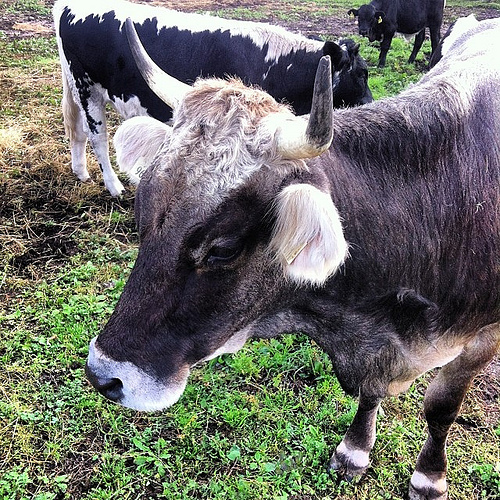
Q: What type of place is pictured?
A: It is a field.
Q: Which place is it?
A: It is a field.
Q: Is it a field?
A: Yes, it is a field.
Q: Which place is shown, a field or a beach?
A: It is a field.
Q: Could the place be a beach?
A: No, it is a field.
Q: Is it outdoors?
A: Yes, it is outdoors.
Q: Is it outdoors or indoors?
A: It is outdoors.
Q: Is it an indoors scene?
A: No, it is outdoors.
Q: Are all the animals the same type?
A: Yes, all the animals are cows.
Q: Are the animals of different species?
A: No, all the animals are cows.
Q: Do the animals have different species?
A: No, all the animals are cows.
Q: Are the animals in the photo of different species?
A: No, all the animals are cows.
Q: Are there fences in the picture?
A: No, there are no fences.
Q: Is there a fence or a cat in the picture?
A: No, there are no fences or cats.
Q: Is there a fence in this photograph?
A: No, there are no fences.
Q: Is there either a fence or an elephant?
A: No, there are no fences or elephants.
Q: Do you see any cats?
A: No, there are no cats.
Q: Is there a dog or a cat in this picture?
A: No, there are no cats or dogs.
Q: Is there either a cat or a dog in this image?
A: No, there are no cats or dogs.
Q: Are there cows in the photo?
A: Yes, there is a cow.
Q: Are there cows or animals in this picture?
A: Yes, there is a cow.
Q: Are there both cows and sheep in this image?
A: No, there is a cow but no sheep.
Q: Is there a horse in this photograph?
A: No, there are no horses.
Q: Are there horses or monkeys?
A: No, there are no horses or monkeys.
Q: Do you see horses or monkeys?
A: No, there are no horses or monkeys.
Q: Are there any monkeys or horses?
A: No, there are no horses or monkeys.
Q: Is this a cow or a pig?
A: This is a cow.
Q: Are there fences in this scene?
A: No, there are no fences.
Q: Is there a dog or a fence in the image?
A: No, there are no fences or dogs.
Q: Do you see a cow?
A: Yes, there is a cow.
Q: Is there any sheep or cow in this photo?
A: Yes, there is a cow.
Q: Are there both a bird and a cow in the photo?
A: No, there is a cow but no birds.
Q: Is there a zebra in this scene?
A: No, there are no zebras.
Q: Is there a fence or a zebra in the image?
A: No, there are no zebras or fences.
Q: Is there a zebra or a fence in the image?
A: No, there are no zebras or fences.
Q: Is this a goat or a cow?
A: This is a cow.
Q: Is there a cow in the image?
A: Yes, there is a cow.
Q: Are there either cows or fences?
A: Yes, there is a cow.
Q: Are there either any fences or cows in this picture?
A: Yes, there is a cow.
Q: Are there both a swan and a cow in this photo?
A: No, there is a cow but no swans.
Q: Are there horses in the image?
A: No, there are no horses.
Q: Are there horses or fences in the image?
A: No, there are no horses or fences.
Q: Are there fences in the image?
A: No, there are no fences.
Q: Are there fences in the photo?
A: No, there are no fences.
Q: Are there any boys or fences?
A: No, there are no fences or boys.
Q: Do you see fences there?
A: No, there are no fences.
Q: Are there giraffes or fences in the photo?
A: No, there are no fences or giraffes.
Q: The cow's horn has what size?
A: The horn is large.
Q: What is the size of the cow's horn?
A: The horn is large.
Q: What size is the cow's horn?
A: The horn is large.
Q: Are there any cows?
A: Yes, there is a cow.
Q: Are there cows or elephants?
A: Yes, there is a cow.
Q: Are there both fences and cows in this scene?
A: No, there is a cow but no fences.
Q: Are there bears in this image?
A: No, there are no bears.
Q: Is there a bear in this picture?
A: No, there are no bears.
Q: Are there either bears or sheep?
A: No, there are no bears or sheep.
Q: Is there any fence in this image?
A: No, there are no fences.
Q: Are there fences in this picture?
A: No, there are no fences.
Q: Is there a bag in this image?
A: No, there are no bags.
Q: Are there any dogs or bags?
A: No, there are no bags or dogs.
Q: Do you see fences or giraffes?
A: No, there are no fences or giraffes.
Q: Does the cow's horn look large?
A: Yes, the horn is large.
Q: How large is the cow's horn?
A: The horn is large.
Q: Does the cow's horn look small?
A: No, the horn is large.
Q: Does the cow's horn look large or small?
A: The horn is large.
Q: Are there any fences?
A: No, there are no fences.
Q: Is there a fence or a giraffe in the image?
A: No, there are no fences or giraffes.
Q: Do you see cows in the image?
A: Yes, there is a cow.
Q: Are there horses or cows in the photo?
A: Yes, there is a cow.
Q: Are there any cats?
A: No, there are no cats.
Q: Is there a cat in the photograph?
A: No, there are no cats.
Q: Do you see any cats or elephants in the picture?
A: No, there are no cats or elephants.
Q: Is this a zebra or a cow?
A: This is a cow.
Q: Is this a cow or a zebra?
A: This is a cow.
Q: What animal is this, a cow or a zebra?
A: This is a cow.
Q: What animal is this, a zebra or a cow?
A: This is a cow.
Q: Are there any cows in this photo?
A: Yes, there is a cow.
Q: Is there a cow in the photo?
A: Yes, there is a cow.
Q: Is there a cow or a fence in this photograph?
A: Yes, there is a cow.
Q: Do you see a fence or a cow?
A: Yes, there is a cow.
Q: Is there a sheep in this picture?
A: No, there is no sheep.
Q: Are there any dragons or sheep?
A: No, there are no sheep or dragons.